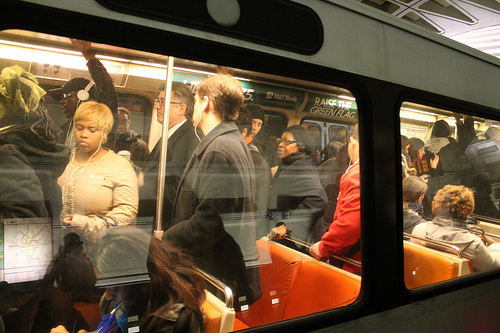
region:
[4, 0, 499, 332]
subway car with passengers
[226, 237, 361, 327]
orange seat in subway car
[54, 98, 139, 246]
young woman with earphones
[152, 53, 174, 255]
pole for passengers to hold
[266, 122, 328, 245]
woman wearing glasses and hat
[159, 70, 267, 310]
man standing in subway car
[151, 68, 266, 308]
man wearing earphones and dark jacket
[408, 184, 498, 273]
woman sitting in subway car seat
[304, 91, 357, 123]
advertisement inside subway car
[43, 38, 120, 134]
man holding rail and wearing earphones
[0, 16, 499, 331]
People standing in a subway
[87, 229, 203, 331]
A woman with brown hair sitting down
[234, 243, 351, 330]
An empty orange seat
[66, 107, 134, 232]
A woman with white earbuds in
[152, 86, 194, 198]
A man dressed in a suit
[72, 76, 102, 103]
A pair of white headphones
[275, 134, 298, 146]
A pair of black glasses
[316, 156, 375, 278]
A man wearing a red jacket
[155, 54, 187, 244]
A pole on the subway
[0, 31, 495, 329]
The windows alongside the subway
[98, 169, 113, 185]
woman wearing beige shirt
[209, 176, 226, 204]
man wearing black shirt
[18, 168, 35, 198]
man wearing black coat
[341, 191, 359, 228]
woman wearing red coat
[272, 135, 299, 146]
woman wearing black shades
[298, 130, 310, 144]
woman with black scarf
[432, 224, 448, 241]
woman wearing white jacket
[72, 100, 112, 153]
Woman with short dyed blond hair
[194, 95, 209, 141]
Man wearing white earbud headphones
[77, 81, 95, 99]
Man wearing over-the-ears white headphones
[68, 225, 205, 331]
Woman sitting down and looking down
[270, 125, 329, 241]
Woman standing holding on to bar on back of seat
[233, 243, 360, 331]
Orange seat on public transportation vehicle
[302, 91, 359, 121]
Advertisement inside public transportation vehicle saying "raise the green flag"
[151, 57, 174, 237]
Pole for standings passengers to hold onto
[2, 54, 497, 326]
Passengers inside a crowded train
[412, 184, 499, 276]
Woman sitting down on train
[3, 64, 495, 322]
people inside the train car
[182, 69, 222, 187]
man with ear phones in his ear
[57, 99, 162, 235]
blond hair on woman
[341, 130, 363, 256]
person with orange jacket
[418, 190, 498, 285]
woman sitting with her back against seat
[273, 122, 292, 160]
woman with glasses on face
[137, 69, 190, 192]
man with glasses onface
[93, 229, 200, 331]
girl looking down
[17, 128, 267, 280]
reflection on the train window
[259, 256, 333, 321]
seat is colored orange